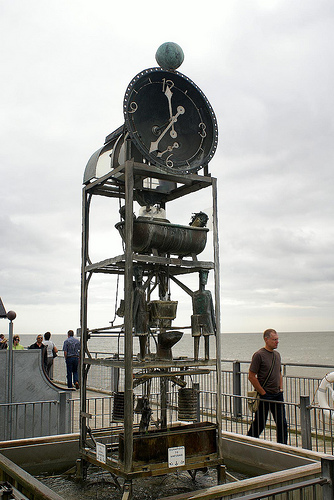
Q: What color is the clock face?
A: Black.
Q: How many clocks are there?
A: One.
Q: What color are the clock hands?
A: Silver.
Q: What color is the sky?
A: Gray.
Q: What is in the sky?
A: Clouds.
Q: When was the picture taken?
A: Daytime.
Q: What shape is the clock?
A: Circle.